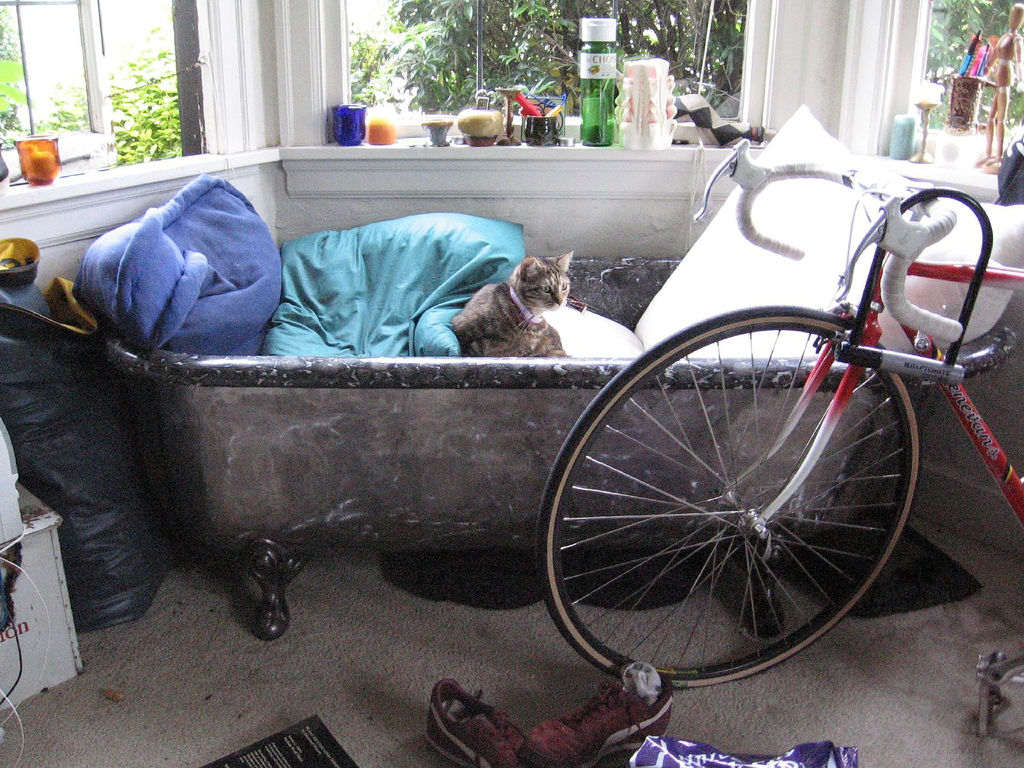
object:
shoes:
[541, 651, 687, 752]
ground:
[0, 525, 1018, 765]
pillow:
[76, 171, 293, 362]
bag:
[0, 299, 173, 635]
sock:
[621, 655, 671, 705]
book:
[186, 709, 380, 765]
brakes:
[684, 134, 764, 232]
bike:
[528, 135, 1023, 741]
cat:
[451, 247, 593, 362]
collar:
[493, 280, 554, 321]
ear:
[517, 250, 549, 280]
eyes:
[535, 283, 556, 295]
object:
[411, 93, 461, 163]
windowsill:
[870, 136, 1013, 231]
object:
[877, 98, 923, 185]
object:
[559, 134, 583, 147]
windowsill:
[276, 108, 783, 191]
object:
[506, 104, 561, 160]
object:
[681, 93, 745, 147]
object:
[451, 93, 509, 169]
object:
[12, 135, 67, 186]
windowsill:
[3, 160, 267, 206]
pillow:
[269, 219, 524, 369]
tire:
[528, 286, 942, 727]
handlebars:
[867, 194, 964, 340]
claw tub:
[98, 289, 883, 665]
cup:
[317, 96, 369, 148]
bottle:
[577, 1, 627, 155]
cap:
[573, 13, 623, 50]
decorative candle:
[607, 41, 687, 167]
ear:
[548, 245, 583, 275]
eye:
[551, 275, 571, 299]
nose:
[544, 288, 572, 308]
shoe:
[399, 662, 561, 766]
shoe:
[958, 621, 1023, 766]